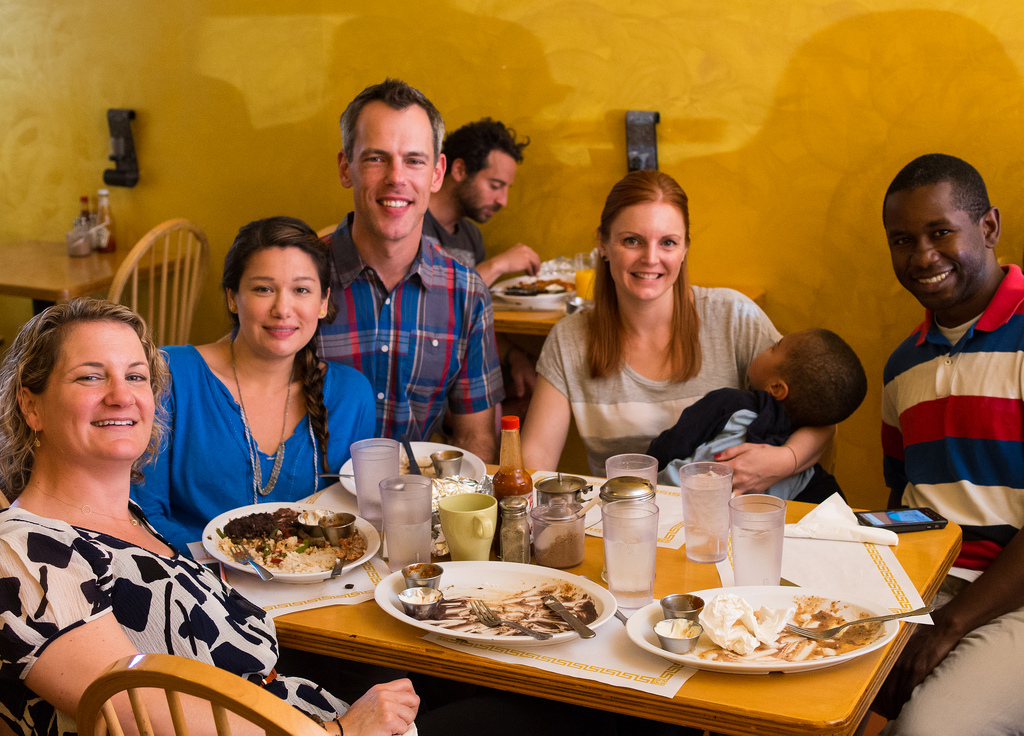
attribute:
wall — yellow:
[733, 32, 863, 133]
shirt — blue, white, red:
[942, 370, 1000, 448]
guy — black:
[872, 190, 995, 289]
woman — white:
[593, 194, 749, 325]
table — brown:
[40, 237, 118, 275]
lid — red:
[496, 401, 529, 441]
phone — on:
[839, 479, 967, 583]